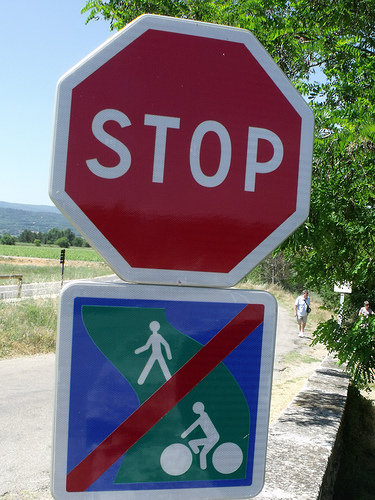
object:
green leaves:
[369, 388, 372, 392]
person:
[294, 289, 311, 337]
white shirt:
[295, 296, 311, 317]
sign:
[46, 13, 317, 289]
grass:
[1, 293, 58, 353]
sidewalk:
[0, 359, 54, 499]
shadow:
[279, 391, 347, 429]